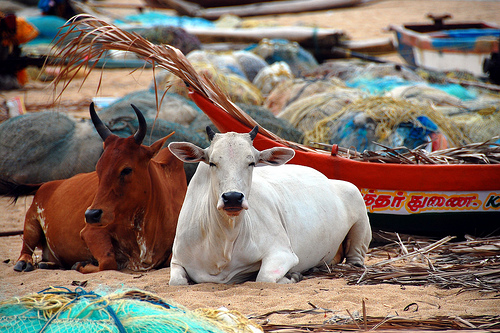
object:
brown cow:
[13, 101, 195, 274]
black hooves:
[10, 261, 38, 274]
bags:
[270, 37, 500, 134]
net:
[202, 42, 496, 158]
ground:
[14, 261, 356, 314]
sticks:
[369, 227, 499, 322]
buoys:
[0, 287, 225, 332]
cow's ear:
[257, 146, 295, 166]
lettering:
[352, 190, 495, 219]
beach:
[1, 1, 497, 329]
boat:
[386, 12, 500, 84]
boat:
[175, 78, 500, 238]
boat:
[11, 15, 348, 57]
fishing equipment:
[1, 282, 261, 332]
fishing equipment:
[304, 96, 454, 153]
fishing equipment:
[0, 110, 104, 195]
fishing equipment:
[89, 88, 304, 142]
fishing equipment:
[254, 60, 293, 89]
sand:
[210, 290, 462, 313]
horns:
[206, 126, 215, 141]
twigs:
[242, 308, 445, 331]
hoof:
[70, 262, 81, 270]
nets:
[290, 90, 400, 152]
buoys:
[290, 81, 467, 164]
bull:
[156, 119, 375, 285]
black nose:
[221, 190, 244, 206]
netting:
[5, 274, 169, 312]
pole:
[63, 25, 347, 41]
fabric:
[29, 8, 209, 60]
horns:
[88, 102, 112, 139]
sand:
[6, 195, 70, 288]